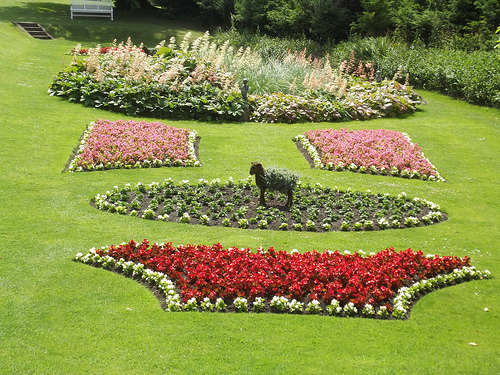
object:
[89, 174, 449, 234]
patch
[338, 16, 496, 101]
shrubery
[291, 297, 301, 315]
flower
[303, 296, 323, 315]
flower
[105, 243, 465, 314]
flower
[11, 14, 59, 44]
stairs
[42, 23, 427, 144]
flowers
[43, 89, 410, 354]
grass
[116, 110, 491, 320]
flowers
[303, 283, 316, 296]
flower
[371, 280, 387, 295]
flower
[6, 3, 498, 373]
ground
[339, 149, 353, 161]
flower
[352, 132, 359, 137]
flower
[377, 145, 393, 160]
flower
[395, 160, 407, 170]
flower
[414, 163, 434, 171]
flower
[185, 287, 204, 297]
flower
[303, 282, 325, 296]
flower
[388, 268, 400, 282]
flower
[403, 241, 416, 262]
flower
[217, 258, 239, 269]
flower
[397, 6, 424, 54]
trees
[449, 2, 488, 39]
trees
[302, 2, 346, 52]
trees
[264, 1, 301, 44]
trees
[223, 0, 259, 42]
trees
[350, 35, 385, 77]
bushes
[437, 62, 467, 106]
bushes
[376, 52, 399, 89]
bushes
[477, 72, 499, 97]
bushes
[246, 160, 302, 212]
animal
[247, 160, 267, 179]
head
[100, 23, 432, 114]
plants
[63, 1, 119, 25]
bench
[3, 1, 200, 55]
hill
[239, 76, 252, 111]
statue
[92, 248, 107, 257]
flower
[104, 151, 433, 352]
back